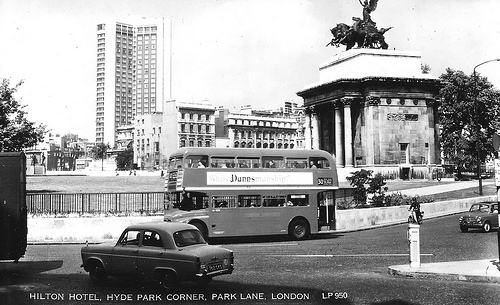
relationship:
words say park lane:
[30, 289, 357, 304] [214, 292, 272, 303]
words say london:
[30, 289, 357, 304] [271, 293, 313, 302]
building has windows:
[97, 14, 162, 159] [115, 26, 155, 129]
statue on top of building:
[332, 0, 397, 50] [306, 55, 443, 165]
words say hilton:
[30, 289, 357, 304] [26, 291, 66, 302]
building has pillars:
[306, 55, 443, 165] [299, 103, 353, 168]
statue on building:
[332, 0, 397, 50] [306, 55, 443, 165]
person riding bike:
[409, 197, 425, 223] [408, 207, 423, 224]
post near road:
[472, 53, 500, 185] [97, 215, 498, 277]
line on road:
[274, 240, 425, 264] [97, 215, 498, 277]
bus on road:
[165, 147, 345, 238] [97, 215, 498, 277]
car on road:
[85, 213, 238, 280] [97, 215, 498, 277]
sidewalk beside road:
[406, 173, 485, 199] [97, 215, 498, 277]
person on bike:
[409, 197, 425, 223] [411, 213, 429, 224]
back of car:
[172, 250, 239, 275] [85, 213, 238, 280]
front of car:
[84, 237, 132, 273] [85, 213, 238, 280]